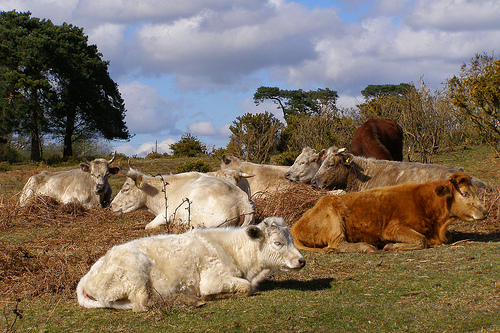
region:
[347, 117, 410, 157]
a brown cow standing up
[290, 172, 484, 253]
a light brown cow laying down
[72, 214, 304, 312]
a white cow laying down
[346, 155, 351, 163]
a yellow tag in a cow's ear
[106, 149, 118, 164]
a horn on a cow's head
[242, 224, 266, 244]
the ear of a cow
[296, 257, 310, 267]
the dark brown nose of a cow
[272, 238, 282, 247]
the eye of a cow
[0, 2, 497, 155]
a cloudy blue sky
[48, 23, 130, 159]
a dark green leafy tree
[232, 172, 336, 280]
the head of a cow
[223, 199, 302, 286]
the head of a cow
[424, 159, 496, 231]
the head of a cow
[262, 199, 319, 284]
the head of a cow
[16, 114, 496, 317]
A bunch of cows lying in the grass.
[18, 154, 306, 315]
Five whitish cows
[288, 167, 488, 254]
A brown cow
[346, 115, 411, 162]
The rear of a dark brown cow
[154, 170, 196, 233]
A twig of a branch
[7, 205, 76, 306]
Hay on the ground.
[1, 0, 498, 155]
A cloud filled sky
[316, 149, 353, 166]
Tags on a cow's ears.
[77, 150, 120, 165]
A cow's horns.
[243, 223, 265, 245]
A cow's ear.